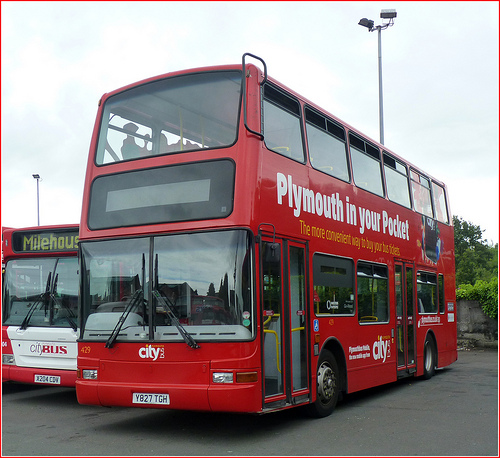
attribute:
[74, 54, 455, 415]
bus — red, double-decker, tall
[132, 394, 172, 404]
license — white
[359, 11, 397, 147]
pole — tall, gray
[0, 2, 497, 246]
sky — white, cloudy, blue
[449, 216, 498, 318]
tree — green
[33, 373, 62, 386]
plate — white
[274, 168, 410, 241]
sign — white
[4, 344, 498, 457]
street — gray